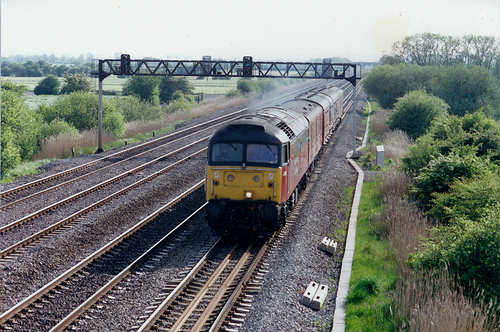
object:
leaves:
[397, 96, 420, 109]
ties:
[300, 282, 328, 309]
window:
[244, 143, 280, 166]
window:
[211, 143, 245, 165]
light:
[245, 191, 252, 197]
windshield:
[206, 139, 281, 168]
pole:
[89, 54, 359, 84]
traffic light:
[118, 53, 129, 74]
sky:
[1, 1, 482, 66]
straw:
[379, 118, 479, 330]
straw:
[33, 131, 104, 158]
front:
[202, 122, 287, 232]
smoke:
[248, 74, 309, 108]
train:
[204, 78, 353, 241]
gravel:
[288, 238, 320, 272]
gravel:
[132, 253, 182, 287]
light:
[241, 57, 253, 77]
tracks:
[6, 89, 342, 318]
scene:
[1, 7, 491, 321]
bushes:
[360, 56, 499, 331]